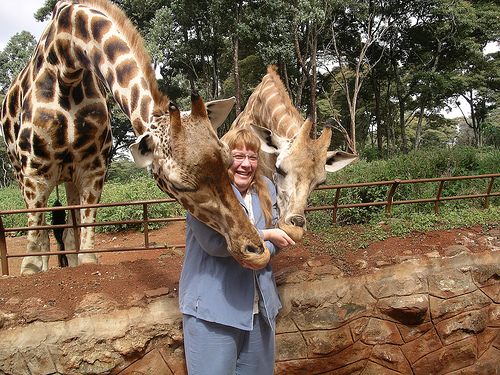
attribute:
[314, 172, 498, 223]
fence — metal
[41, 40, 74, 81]
spot — brown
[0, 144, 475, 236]
bushes — short, green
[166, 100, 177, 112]
horn tip — black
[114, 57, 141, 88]
spot — brown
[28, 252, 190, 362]
dirt — brown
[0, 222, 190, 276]
path — dirt, behind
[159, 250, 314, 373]
pants — blue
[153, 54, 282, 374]
woman — standing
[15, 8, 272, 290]
giraffe — brown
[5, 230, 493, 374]
wall — stone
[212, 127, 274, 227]
hair — long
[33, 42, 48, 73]
spot — brown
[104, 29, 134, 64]
spot — brown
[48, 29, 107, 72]
spot — brown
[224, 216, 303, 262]
hand — under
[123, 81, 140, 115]
spot — brown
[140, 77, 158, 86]
spot — brown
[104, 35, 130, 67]
spot — brown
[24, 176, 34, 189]
spot — brown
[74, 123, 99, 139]
spot — brown